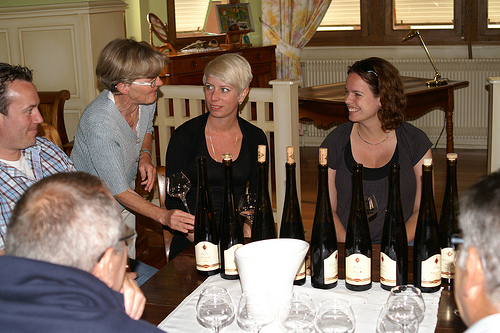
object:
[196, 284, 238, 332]
wine glass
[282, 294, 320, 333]
wine glass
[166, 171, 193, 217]
wine glass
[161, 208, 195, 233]
hand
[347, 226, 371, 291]
wine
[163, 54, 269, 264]
lady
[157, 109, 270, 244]
shirt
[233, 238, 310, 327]
bucket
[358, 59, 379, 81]
sunglasses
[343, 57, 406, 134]
head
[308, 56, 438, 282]
woman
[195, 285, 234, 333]
empty gass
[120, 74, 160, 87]
glasses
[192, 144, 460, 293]
wine bottles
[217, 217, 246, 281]
wine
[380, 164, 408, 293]
bottles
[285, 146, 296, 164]
corks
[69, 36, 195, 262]
people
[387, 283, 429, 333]
glasses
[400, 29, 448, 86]
lamp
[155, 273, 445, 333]
tablecloth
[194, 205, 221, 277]
wine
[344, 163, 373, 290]
bottle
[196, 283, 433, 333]
row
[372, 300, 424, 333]
glass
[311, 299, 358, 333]
glass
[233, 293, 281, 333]
glass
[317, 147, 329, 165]
cork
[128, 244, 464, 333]
table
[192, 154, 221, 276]
bottle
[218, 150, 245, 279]
bottle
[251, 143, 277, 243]
bottle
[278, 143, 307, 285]
bottle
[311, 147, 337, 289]
bottle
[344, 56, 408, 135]
hair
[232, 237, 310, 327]
vase